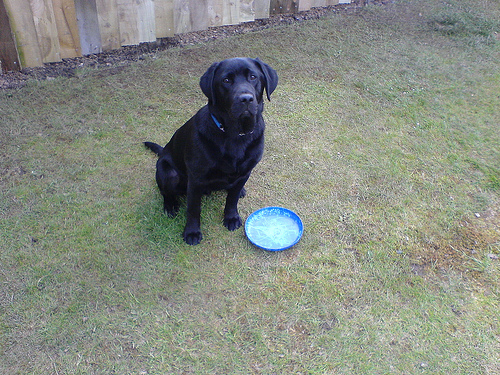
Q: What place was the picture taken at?
A: It was taken at the yard.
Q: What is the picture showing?
A: It is showing a yard.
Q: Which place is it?
A: It is a yard.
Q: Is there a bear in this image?
A: No, there are no bears.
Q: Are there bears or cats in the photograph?
A: No, there are no bears or cats.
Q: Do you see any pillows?
A: No, there are no pillows.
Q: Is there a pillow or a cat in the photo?
A: No, there are no pillows or cats.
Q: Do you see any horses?
A: No, there are no horses.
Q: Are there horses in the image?
A: No, there are no horses.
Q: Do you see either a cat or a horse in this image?
A: No, there are no horses or cats.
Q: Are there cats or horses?
A: No, there are no horses or cats.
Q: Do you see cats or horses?
A: No, there are no horses or cats.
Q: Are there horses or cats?
A: No, there are no horses or cats.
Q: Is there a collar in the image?
A: Yes, there is a collar.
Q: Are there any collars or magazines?
A: Yes, there is a collar.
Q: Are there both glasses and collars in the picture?
A: No, there is a collar but no glasses.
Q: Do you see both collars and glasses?
A: No, there is a collar but no glasses.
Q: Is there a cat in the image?
A: No, there are no cats.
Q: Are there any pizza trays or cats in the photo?
A: No, there are no cats or pizza trays.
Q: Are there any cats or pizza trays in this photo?
A: No, there are no cats or pizza trays.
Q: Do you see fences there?
A: Yes, there is a fence.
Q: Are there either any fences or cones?
A: Yes, there is a fence.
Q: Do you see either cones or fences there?
A: Yes, there is a fence.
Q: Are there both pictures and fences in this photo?
A: No, there is a fence but no pictures.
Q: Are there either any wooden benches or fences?
A: Yes, there is a wood fence.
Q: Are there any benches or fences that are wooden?
A: Yes, the fence is wooden.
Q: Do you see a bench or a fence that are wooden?
A: Yes, the fence is wooden.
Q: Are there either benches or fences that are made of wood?
A: Yes, the fence is made of wood.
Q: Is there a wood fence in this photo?
A: Yes, there is a wood fence.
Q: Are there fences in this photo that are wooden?
A: Yes, there is a fence that is wooden.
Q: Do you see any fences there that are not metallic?
A: Yes, there is a wooden fence.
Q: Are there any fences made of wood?
A: Yes, there is a fence that is made of wood.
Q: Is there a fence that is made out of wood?
A: Yes, there is a fence that is made of wood.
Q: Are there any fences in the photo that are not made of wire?
A: Yes, there is a fence that is made of wood.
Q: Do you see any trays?
A: No, there are no trays.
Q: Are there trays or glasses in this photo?
A: No, there are no trays or glasses.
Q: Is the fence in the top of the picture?
A: Yes, the fence is in the top of the image.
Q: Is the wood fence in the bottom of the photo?
A: No, the fence is in the top of the image.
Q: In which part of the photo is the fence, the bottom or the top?
A: The fence is in the top of the image.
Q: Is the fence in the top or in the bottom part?
A: The fence is in the top of the image.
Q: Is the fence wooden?
A: Yes, the fence is wooden.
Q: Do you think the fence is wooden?
A: Yes, the fence is wooden.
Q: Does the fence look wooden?
A: Yes, the fence is wooden.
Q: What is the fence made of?
A: The fence is made of wood.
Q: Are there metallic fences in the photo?
A: No, there is a fence but it is wooden.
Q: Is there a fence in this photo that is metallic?
A: No, there is a fence but it is wooden.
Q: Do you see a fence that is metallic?
A: No, there is a fence but it is wooden.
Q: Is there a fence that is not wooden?
A: No, there is a fence but it is wooden.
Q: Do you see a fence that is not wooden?
A: No, there is a fence but it is wooden.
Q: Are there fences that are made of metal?
A: No, there is a fence but it is made of wood.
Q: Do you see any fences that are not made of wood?
A: No, there is a fence but it is made of wood.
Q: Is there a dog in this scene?
A: Yes, there is a dog.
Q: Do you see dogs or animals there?
A: Yes, there is a dog.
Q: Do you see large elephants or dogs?
A: Yes, there is a large dog.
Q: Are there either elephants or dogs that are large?
A: Yes, the dog is large.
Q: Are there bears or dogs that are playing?
A: Yes, the dog is playing.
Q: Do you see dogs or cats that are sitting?
A: Yes, the dog is sitting.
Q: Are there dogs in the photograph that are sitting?
A: Yes, there is a dog that is sitting.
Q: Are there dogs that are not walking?
A: Yes, there is a dog that is sitting.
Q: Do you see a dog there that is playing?
A: Yes, there is a dog that is playing.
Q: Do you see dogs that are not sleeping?
A: Yes, there is a dog that is playing .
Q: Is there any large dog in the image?
A: Yes, there is a large dog.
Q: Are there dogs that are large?
A: Yes, there is a dog that is large.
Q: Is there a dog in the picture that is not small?
A: Yes, there is a large dog.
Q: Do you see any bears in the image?
A: No, there are no bears.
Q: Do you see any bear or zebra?
A: No, there are no bears or zebras.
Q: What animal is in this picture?
A: The animal is a dog.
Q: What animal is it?
A: The animal is a dog.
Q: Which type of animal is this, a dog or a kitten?
A: This is a dog.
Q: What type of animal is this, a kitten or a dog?
A: This is a dog.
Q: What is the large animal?
A: The animal is a dog.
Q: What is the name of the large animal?
A: The animal is a dog.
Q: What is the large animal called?
A: The animal is a dog.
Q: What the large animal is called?
A: The animal is a dog.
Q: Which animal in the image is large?
A: The animal is a dog.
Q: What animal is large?
A: The animal is a dog.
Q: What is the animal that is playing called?
A: The animal is a dog.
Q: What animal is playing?
A: The animal is a dog.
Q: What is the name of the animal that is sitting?
A: The animal is a dog.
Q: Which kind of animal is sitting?
A: The animal is a dog.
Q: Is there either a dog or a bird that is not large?
A: No, there is a dog but it is large.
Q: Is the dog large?
A: Yes, the dog is large.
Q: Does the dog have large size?
A: Yes, the dog is large.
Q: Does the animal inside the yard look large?
A: Yes, the dog is large.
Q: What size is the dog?
A: The dog is large.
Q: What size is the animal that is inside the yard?
A: The dog is large.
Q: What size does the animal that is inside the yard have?
A: The dog has large size.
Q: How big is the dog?
A: The dog is large.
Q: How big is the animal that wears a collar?
A: The dog is large.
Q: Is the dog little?
A: No, the dog is large.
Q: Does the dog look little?
A: No, the dog is large.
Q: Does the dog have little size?
A: No, the dog is large.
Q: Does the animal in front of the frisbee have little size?
A: No, the dog is large.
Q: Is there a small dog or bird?
A: No, there is a dog but it is large.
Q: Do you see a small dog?
A: No, there is a dog but it is large.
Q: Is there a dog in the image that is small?
A: No, there is a dog but it is large.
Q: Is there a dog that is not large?
A: No, there is a dog but it is large.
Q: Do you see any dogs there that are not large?
A: No, there is a dog but it is large.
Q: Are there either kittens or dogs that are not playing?
A: No, there is a dog but it is playing.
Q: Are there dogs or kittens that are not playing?
A: No, there is a dog but it is playing.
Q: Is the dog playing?
A: Yes, the dog is playing.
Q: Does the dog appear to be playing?
A: Yes, the dog is playing.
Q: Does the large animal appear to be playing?
A: Yes, the dog is playing.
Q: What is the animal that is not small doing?
A: The dog is playing.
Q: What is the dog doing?
A: The dog is playing.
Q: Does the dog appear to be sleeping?
A: No, the dog is playing.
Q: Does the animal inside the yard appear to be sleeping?
A: No, the dog is playing.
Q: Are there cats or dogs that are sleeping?
A: No, there is a dog but it is playing.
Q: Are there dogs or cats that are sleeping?
A: No, there is a dog but it is playing.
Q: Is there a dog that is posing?
A: No, there is a dog but it is playing.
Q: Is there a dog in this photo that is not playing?
A: No, there is a dog but it is playing.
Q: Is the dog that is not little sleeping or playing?
A: The dog is playing.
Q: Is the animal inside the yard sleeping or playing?
A: The dog is playing.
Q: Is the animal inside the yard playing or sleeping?
A: The dog is playing.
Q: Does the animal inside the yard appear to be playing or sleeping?
A: The dog is playing.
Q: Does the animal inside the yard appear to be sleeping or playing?
A: The dog is playing.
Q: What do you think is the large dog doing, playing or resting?
A: The dog is playing.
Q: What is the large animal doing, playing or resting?
A: The dog is playing.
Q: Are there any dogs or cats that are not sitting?
A: No, there is a dog but it is sitting.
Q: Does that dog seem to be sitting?
A: Yes, the dog is sitting.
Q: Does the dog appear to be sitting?
A: Yes, the dog is sitting.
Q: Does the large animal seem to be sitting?
A: Yes, the dog is sitting.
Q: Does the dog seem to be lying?
A: No, the dog is sitting.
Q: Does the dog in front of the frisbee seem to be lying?
A: No, the dog is sitting.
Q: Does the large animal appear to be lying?
A: No, the dog is sitting.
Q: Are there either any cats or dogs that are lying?
A: No, there is a dog but it is sitting.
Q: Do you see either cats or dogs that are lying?
A: No, there is a dog but it is sitting.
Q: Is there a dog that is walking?
A: No, there is a dog but it is sitting.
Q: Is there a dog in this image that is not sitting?
A: No, there is a dog but it is sitting.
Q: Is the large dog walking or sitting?
A: The dog is sitting.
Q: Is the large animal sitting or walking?
A: The dog is sitting.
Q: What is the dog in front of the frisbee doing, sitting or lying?
A: The dog is sitting.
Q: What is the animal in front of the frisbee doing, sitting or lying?
A: The dog is sitting.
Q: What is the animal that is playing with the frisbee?
A: The animal is a dog.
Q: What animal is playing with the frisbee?
A: The animal is a dog.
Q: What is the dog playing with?
A: The dog is playing with a frisbee.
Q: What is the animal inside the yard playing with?
A: The dog is playing with a frisbee.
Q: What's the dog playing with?
A: The dog is playing with a frisbee.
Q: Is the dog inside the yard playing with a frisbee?
A: Yes, the dog is playing with a frisbee.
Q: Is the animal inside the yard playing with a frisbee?
A: Yes, the dog is playing with a frisbee.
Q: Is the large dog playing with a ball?
A: No, the dog is playing with a frisbee.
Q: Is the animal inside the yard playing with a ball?
A: No, the dog is playing with a frisbee.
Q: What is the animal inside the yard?
A: The animal is a dog.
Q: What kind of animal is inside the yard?
A: The animal is a dog.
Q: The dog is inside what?
A: The dog is inside the yard.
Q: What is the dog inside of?
A: The dog is inside the yard.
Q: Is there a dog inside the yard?
A: Yes, there is a dog inside the yard.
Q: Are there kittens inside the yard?
A: No, there is a dog inside the yard.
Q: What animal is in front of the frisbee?
A: The dog is in front of the frisbee.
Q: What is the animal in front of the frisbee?
A: The animal is a dog.